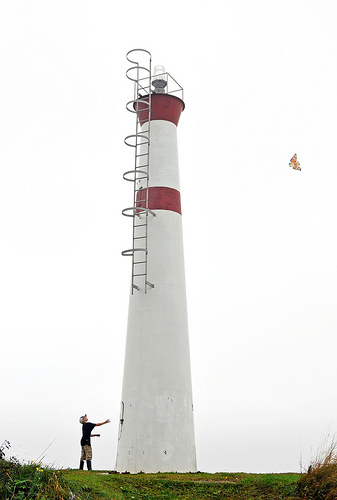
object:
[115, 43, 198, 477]
lighthouse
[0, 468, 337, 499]
field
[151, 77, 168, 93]
light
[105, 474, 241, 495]
grass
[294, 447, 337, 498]
bush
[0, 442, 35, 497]
bush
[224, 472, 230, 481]
flowers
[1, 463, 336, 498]
bank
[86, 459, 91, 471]
boots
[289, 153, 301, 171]
kite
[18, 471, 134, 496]
grass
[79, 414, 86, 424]
hat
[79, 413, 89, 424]
head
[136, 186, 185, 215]
red stripe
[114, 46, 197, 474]
building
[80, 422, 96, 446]
black t-shirt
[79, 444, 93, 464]
pants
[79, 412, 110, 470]
boy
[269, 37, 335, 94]
sky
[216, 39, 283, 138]
foggy climate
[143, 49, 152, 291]
railing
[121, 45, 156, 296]
ladder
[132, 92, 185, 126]
top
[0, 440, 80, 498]
vegetation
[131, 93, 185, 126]
stripes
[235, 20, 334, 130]
clouds